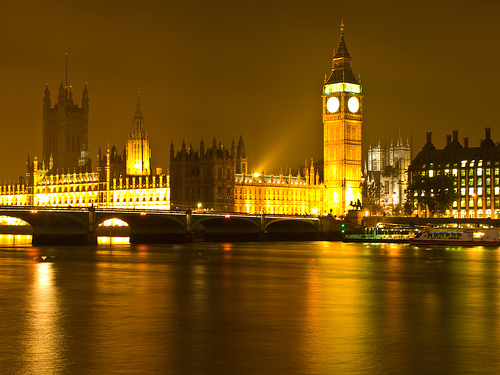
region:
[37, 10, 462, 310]
London at night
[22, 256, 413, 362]
night lights on the water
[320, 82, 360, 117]
two clock faces on a tower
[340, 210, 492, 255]
tour ships at their moorings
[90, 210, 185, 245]
archway of a bridge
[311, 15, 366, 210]
icon known as Big Ben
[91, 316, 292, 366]
calm river water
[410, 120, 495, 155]
darkened roof of a building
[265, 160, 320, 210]
brightly lit facade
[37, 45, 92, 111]
lights on the spires of a building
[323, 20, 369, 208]
a larger clock tower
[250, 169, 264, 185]
a spot light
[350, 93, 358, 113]
a clock on the tower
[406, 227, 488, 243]
boats on the water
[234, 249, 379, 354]
reflection of light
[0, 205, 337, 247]
concert bridge over water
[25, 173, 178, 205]
bright lights on building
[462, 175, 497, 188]
a row of windows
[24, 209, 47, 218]
signal lights on a bridge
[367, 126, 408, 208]
a castle in the back ground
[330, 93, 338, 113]
The clock on the building facing left.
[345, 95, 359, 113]
The clock on the building facing right.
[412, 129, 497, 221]
The building farthest right.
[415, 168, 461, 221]
The trees in front of the building that is farthest right.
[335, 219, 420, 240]
The white boat in the water.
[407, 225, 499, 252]
The boat with red on it in the water.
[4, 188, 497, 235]
The bridge above the water.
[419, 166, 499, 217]
The windows on the building furthest right.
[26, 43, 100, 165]
The tall building furthest left.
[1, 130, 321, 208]
The building shaped like a castle to the left of the building with the clocks on it.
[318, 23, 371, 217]
The structure housing Big Ben.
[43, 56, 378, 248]
The Houses of Parliament in London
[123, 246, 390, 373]
The Thames River at night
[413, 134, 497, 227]
Lights are on in the building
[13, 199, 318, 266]
A bridge along the river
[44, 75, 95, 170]
A tower on a building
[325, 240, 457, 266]
Lights reflected in the water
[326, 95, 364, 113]
Two clock faces on the tower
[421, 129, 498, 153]
Multiple chimneys on the roof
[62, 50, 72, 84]
A long, thin spire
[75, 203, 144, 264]
tall arch under the bridge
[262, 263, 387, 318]
light reflecting on the water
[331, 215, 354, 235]
green light on the bridge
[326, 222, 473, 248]
pleasure boat on the water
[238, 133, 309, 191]
spot light in the sky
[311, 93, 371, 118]
Big Ben in the top of building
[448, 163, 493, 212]
windows in the building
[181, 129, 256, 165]
spiral top on building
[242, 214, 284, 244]
base on the bridge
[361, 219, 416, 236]
people standing on the boat